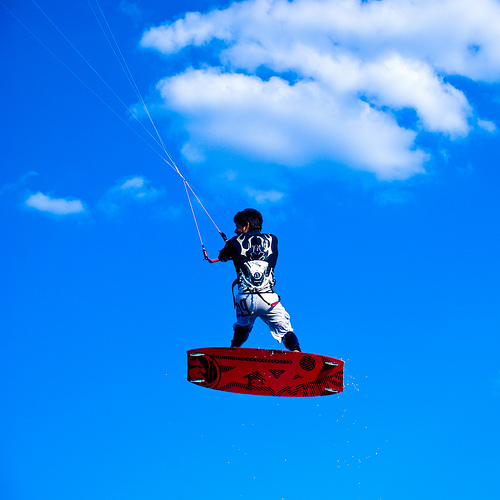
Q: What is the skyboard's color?
A: Red.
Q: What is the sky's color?
A: Blue.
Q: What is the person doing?
A: Skyboarding.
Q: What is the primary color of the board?
A: Red.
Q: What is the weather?
A: Partly cloudy.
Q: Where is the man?
A: Air.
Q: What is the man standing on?
A: Board.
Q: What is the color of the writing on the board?
A: Black.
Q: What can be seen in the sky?
A: Clouds.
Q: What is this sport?
A: Windsurfing.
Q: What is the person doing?
A: Parasailing.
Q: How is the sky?
A: Blue.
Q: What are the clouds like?
A: White.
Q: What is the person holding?
A: Cables.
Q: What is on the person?
A: Harness.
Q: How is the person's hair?
A: Dark.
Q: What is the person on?
A: Board.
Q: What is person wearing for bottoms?
A: Shorts.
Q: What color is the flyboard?
A: Red and black.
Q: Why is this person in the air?
A: Kitesurfing.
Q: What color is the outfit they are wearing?
A: Black and white.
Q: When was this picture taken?
A: Daytime.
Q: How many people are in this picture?
A: One.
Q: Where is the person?
A: In the air.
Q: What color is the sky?
A: Blue.